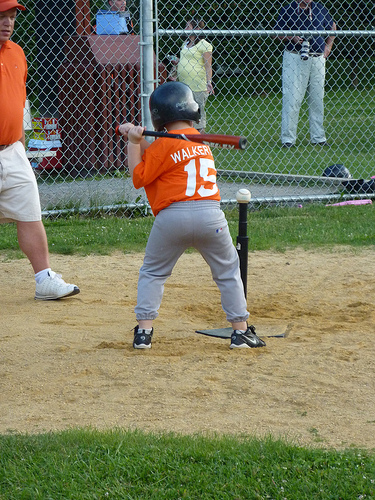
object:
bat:
[297, 204, 302, 208]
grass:
[0, 203, 375, 254]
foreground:
[0, 0, 375, 500]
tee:
[195, 203, 288, 337]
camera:
[300, 35, 314, 60]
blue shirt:
[271, 1, 336, 147]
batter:
[115, 81, 266, 350]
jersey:
[133, 127, 222, 217]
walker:
[170, 145, 212, 163]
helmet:
[149, 81, 202, 140]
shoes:
[34, 270, 81, 300]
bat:
[115, 125, 248, 150]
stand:
[119, 81, 266, 349]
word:
[170, 145, 213, 163]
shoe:
[229, 321, 267, 349]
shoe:
[131, 325, 154, 350]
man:
[0, 0, 79, 301]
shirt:
[0, 39, 27, 145]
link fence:
[137, 0, 161, 144]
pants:
[133, 200, 250, 324]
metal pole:
[158, 29, 374, 36]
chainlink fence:
[9, 0, 375, 216]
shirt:
[275, 0, 334, 57]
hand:
[128, 126, 147, 144]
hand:
[118, 122, 134, 137]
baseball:
[235, 188, 251, 203]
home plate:
[195, 323, 289, 338]